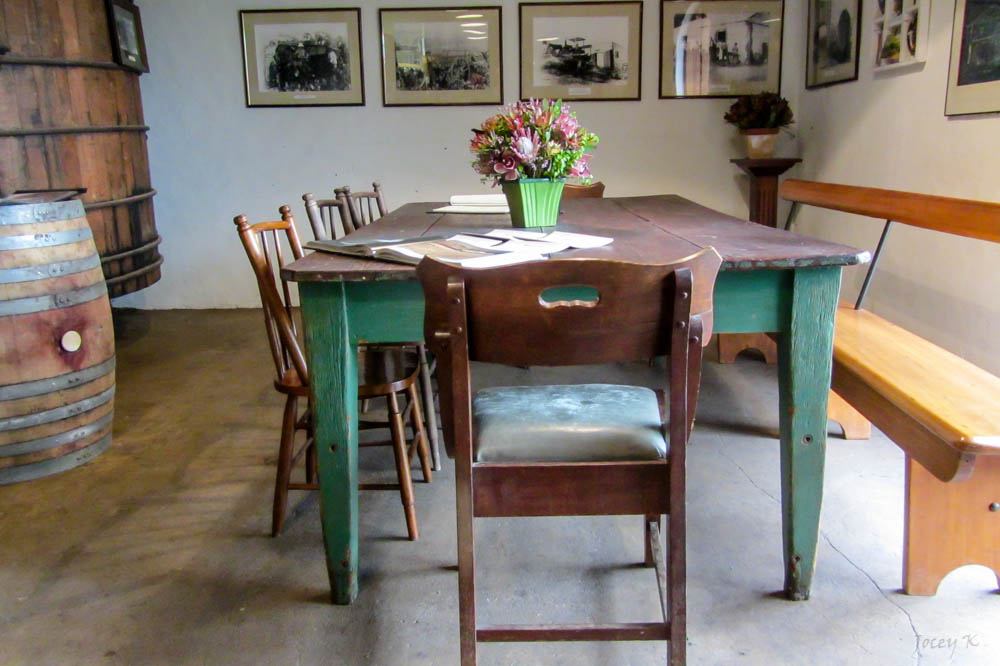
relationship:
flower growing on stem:
[551, 114, 576, 137] [555, 132, 569, 141]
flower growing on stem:
[485, 114, 499, 134] [495, 127, 500, 132]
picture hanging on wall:
[236, 5, 366, 112] [106, 1, 806, 306]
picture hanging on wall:
[375, 5, 504, 108] [106, 1, 806, 306]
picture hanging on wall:
[517, 7, 649, 107] [106, 1, 806, 306]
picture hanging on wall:
[807, 1, 861, 91] [800, 3, 965, 370]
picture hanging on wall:
[869, 1, 932, 75] [800, 3, 965, 370]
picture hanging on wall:
[938, 5, 968, 123] [800, 3, 965, 370]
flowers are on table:
[458, 92, 604, 188] [312, 187, 915, 503]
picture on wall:
[517, 7, 649, 107] [106, 1, 806, 306]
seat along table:
[818, 292, 968, 590] [284, 185, 867, 601]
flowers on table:
[458, 92, 607, 224] [284, 185, 867, 601]